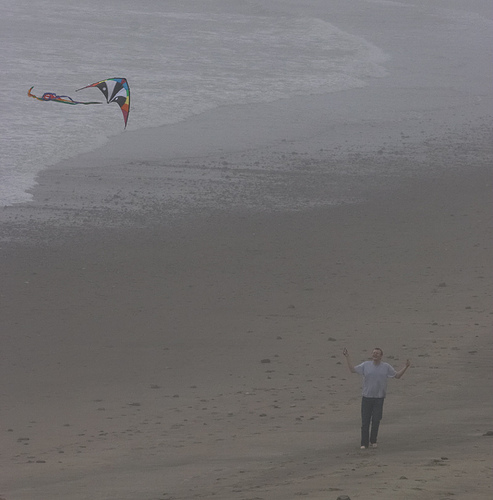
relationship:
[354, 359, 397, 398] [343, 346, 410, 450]
shirt on man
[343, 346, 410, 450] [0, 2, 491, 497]
man walking on beach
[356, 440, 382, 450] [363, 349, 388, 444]
shoes on man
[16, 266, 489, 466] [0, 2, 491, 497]
footprints on beach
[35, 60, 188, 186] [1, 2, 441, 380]
kite flying over beach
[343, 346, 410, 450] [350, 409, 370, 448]
man has leg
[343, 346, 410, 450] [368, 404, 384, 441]
man has leg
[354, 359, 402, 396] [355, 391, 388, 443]
shirt and pants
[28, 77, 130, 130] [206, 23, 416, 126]
kite in air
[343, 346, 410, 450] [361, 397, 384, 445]
man wearing man's pants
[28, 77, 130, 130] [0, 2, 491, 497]
kite flying over beach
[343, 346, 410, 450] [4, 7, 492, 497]
man standing on sand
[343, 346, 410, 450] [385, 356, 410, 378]
man raising arm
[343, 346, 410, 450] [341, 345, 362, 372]
man raising arm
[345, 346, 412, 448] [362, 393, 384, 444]
man wearing pants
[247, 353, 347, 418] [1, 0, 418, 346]
sand on beach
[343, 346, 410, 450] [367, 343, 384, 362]
man has head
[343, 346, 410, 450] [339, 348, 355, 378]
man has arm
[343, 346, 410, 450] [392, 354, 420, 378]
man has arm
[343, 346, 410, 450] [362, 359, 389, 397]
man has body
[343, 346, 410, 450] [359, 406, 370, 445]
man has leg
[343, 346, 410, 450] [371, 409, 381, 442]
man has leg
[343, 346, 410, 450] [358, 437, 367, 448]
man has foot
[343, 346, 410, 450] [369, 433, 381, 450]
man has foot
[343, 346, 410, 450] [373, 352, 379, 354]
man has eye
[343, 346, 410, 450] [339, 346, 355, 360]
man has hand